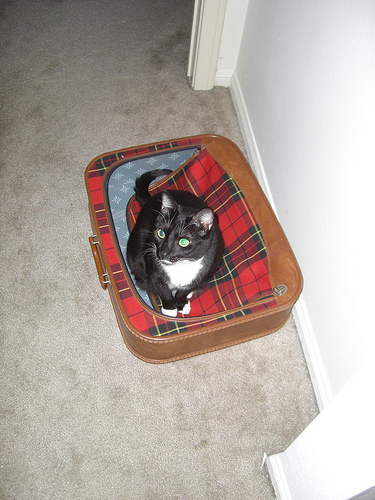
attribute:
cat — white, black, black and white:
[125, 167, 223, 317]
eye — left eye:
[178, 238, 188, 246]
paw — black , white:
[139, 277, 210, 334]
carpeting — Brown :
[20, 50, 287, 448]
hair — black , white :
[175, 195, 204, 310]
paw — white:
[159, 304, 178, 320]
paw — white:
[177, 297, 191, 315]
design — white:
[109, 169, 125, 182]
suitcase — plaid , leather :
[73, 125, 307, 371]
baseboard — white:
[225, 85, 320, 411]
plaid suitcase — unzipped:
[89, 157, 288, 326]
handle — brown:
[86, 231, 111, 292]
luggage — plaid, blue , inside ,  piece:
[82, 131, 306, 363]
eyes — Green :
[156, 227, 189, 250]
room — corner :
[5, 2, 362, 492]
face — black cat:
[156, 203, 209, 263]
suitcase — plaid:
[83, 133, 302, 364]